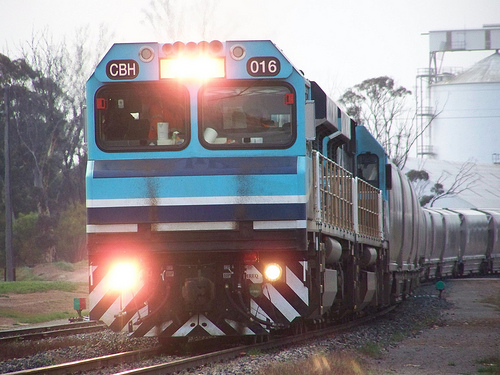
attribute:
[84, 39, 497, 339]
train — black, white, striped, blue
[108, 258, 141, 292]
light — bright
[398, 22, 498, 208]
structure — white, large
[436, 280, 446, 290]
circle — green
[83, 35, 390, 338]
engine — blue, white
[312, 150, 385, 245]
railing — silver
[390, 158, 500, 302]
cars — silver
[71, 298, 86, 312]
reflector — green, red